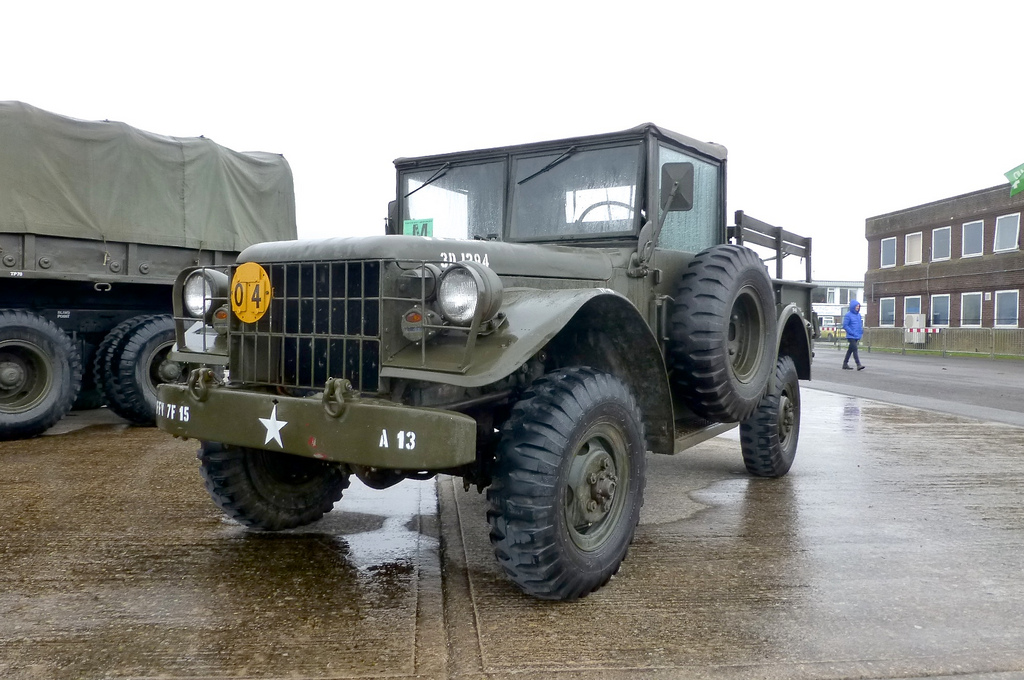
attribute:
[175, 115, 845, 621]
army jeep — olive green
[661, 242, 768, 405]
tire — black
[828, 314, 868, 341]
jacket — blue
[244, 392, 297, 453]
star — white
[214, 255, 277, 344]
circle — yellow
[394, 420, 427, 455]
numbers — white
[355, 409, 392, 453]
letters — white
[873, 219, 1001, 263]
windows — white framed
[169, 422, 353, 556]
wheel — large rubber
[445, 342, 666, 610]
wheel — large rubber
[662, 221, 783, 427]
wheel — large rubber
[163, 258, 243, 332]
headlight — round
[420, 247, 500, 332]
headlight — round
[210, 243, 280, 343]
sign — yellow circle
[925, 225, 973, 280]
window — square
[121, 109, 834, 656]
jeep — military, full view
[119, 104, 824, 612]
jeep — military